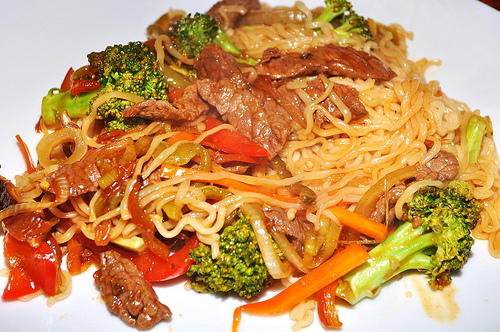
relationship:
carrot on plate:
[239, 241, 369, 316] [2, 2, 498, 331]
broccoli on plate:
[339, 186, 480, 304] [2, 2, 498, 331]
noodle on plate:
[146, 209, 224, 238] [2, 2, 498, 331]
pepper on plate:
[3, 229, 63, 301] [2, 2, 498, 331]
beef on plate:
[194, 44, 292, 160] [2, 2, 498, 331]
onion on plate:
[152, 141, 214, 174] [2, 2, 498, 331]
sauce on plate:
[419, 284, 461, 324] [2, 2, 498, 331]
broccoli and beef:
[339, 186, 480, 304] [194, 44, 292, 160]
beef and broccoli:
[194, 44, 292, 160] [339, 186, 480, 304]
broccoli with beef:
[339, 186, 480, 304] [194, 44, 292, 160]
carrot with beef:
[239, 241, 369, 316] [194, 44, 292, 160]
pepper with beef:
[3, 229, 63, 301] [194, 44, 292, 160]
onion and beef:
[152, 141, 214, 174] [194, 44, 292, 160]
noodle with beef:
[146, 209, 224, 238] [194, 44, 292, 160]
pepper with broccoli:
[3, 229, 63, 301] [339, 186, 480, 304]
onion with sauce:
[152, 141, 214, 174] [419, 284, 461, 324]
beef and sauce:
[194, 44, 292, 160] [419, 284, 461, 324]